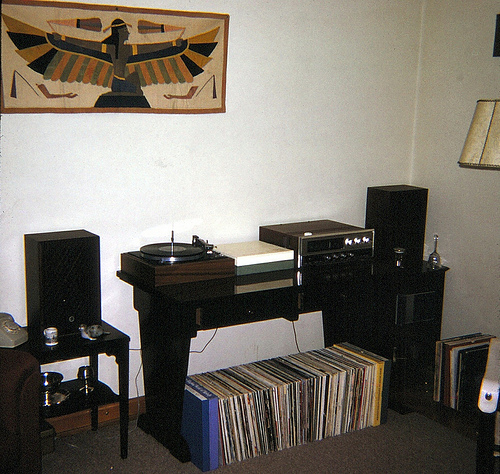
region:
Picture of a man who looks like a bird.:
[1, 2, 241, 129]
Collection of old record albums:
[194, 340, 373, 467]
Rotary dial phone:
[1, 307, 31, 349]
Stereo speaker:
[361, 180, 431, 269]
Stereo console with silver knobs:
[256, 214, 381, 274]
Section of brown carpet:
[319, 436, 438, 472]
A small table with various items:
[26, 314, 138, 470]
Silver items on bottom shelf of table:
[32, 362, 119, 423]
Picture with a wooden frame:
[0, 0, 240, 120]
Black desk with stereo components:
[114, 176, 446, 466]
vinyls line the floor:
[156, 329, 396, 452]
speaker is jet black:
[16, 224, 113, 338]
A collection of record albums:
[183, 339, 389, 471]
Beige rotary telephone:
[0, 310, 31, 349]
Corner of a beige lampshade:
[455, 94, 499, 172]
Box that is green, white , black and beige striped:
[208, 240, 296, 297]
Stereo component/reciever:
[257, 217, 376, 287]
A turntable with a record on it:
[120, 230, 237, 291]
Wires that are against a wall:
[126, 317, 302, 399]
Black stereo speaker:
[22, 226, 102, 345]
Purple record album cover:
[181, 375, 222, 472]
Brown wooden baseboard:
[43, 393, 147, 435]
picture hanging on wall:
[1, 1, 249, 130]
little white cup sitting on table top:
[36, 323, 65, 359]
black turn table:
[126, 232, 233, 312]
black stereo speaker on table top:
[14, 219, 131, 355]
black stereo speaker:
[358, 176, 479, 291]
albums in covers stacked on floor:
[183, 337, 398, 470]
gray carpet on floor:
[163, 441, 377, 471]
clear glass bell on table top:
[422, 217, 449, 276]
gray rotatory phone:
[1, 307, 32, 357]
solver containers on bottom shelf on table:
[40, 366, 129, 417]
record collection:
[200, 340, 398, 457]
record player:
[126, 226, 243, 286]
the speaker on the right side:
[364, 170, 431, 272]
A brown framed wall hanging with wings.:
[1, 1, 231, 113]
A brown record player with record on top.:
[120, 228, 236, 292]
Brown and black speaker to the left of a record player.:
[23, 230, 103, 337]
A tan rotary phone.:
[1, 310, 30, 350]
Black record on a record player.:
[139, 243, 204, 258]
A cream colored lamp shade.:
[458, 97, 498, 169]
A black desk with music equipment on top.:
[113, 259, 450, 463]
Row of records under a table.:
[180, 341, 394, 466]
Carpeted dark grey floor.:
[43, 406, 475, 473]